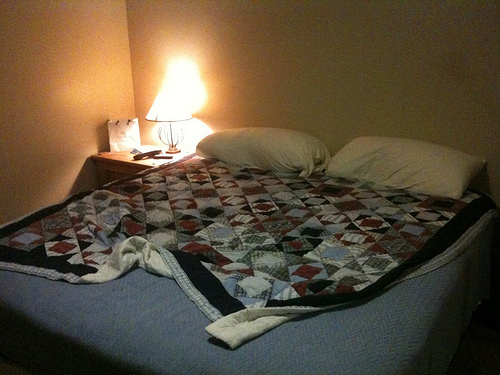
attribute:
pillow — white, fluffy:
[195, 125, 331, 178]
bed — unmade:
[1, 128, 499, 374]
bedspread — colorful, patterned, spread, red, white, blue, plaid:
[0, 148, 499, 349]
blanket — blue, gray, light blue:
[1, 210, 500, 373]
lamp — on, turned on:
[145, 87, 194, 154]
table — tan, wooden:
[90, 142, 194, 182]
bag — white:
[107, 117, 141, 152]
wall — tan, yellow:
[126, 1, 499, 205]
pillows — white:
[195, 125, 487, 199]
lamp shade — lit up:
[144, 91, 195, 122]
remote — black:
[133, 149, 162, 160]